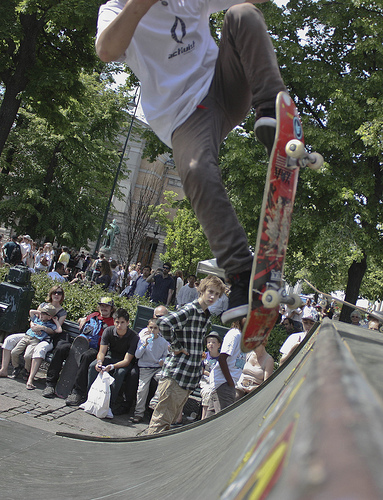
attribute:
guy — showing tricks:
[91, 0, 308, 354]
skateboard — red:
[231, 89, 325, 354]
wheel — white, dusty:
[284, 135, 308, 162]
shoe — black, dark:
[251, 108, 276, 157]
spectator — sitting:
[0, 284, 70, 392]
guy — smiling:
[38, 293, 114, 409]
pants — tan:
[169, 2, 289, 274]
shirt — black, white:
[95, 1, 244, 149]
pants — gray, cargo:
[206, 382, 235, 416]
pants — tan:
[148, 374, 190, 438]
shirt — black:
[94, 324, 141, 361]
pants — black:
[49, 341, 98, 398]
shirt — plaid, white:
[152, 301, 214, 393]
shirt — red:
[81, 309, 115, 350]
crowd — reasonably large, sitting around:
[0, 227, 382, 435]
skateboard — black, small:
[51, 332, 91, 402]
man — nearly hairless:
[122, 302, 172, 427]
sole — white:
[249, 123, 279, 153]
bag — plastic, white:
[78, 369, 118, 420]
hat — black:
[206, 330, 222, 342]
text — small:
[166, 38, 197, 60]